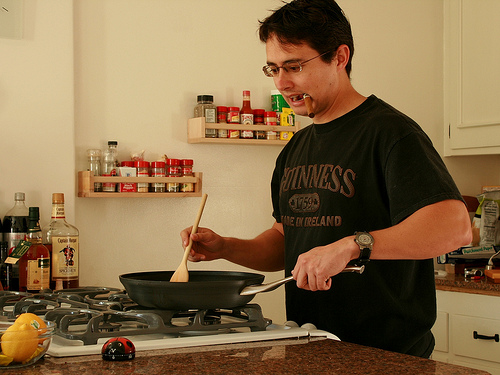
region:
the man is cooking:
[132, 18, 419, 320]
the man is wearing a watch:
[320, 207, 389, 308]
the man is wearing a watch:
[313, 208, 390, 294]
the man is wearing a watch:
[319, 195, 389, 311]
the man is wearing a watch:
[315, 196, 382, 298]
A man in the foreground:
[173, 0, 486, 358]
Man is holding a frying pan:
[108, 188, 370, 313]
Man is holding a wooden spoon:
[150, 182, 230, 293]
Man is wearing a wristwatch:
[338, 222, 384, 262]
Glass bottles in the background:
[13, 189, 84, 294]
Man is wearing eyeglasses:
[260, 35, 351, 77]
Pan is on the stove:
[17, 260, 277, 347]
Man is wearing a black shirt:
[265, 86, 476, 353]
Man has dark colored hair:
[245, 0, 366, 75]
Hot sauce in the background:
[237, 80, 257, 138]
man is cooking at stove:
[180, 0, 471, 355]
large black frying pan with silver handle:
[116, 265, 366, 310]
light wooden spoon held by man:
[170, 190, 210, 281]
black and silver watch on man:
[355, 227, 371, 267]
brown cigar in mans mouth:
[300, 90, 315, 120]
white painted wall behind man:
[0, 0, 441, 325]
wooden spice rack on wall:
[76, 170, 201, 200]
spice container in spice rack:
[120, 165, 135, 190]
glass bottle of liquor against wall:
[41, 191, 76, 286]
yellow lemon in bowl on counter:
[3, 320, 39, 360]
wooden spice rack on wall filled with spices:
[78, 139, 203, 196]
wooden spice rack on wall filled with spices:
[185, 89, 298, 145]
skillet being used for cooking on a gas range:
[116, 265, 366, 315]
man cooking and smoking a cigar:
[178, 3, 468, 364]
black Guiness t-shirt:
[267, 93, 462, 365]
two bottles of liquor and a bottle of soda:
[5, 192, 82, 293]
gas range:
[3, 269, 334, 361]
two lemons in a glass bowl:
[2, 311, 54, 368]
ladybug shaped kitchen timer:
[97, 334, 139, 363]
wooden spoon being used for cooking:
[165, 189, 210, 290]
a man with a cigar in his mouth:
[230, 17, 456, 357]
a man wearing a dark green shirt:
[223, 5, 448, 346]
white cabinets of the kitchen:
[448, 304, 496, 331]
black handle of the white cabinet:
[460, 323, 499, 348]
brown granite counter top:
[281, 347, 347, 372]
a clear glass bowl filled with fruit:
[3, 308, 58, 370]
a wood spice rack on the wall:
[83, 153, 202, 200]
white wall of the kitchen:
[106, 31, 161, 125]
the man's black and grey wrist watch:
[346, 223, 379, 264]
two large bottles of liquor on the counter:
[13, 202, 85, 287]